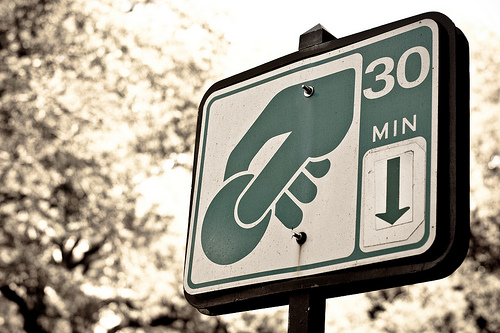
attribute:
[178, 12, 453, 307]
sign — white, green, 30, small, parking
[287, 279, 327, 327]
pole — black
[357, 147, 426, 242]
arrow — green, pointing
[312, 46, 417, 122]
number — white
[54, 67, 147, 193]
tree — black